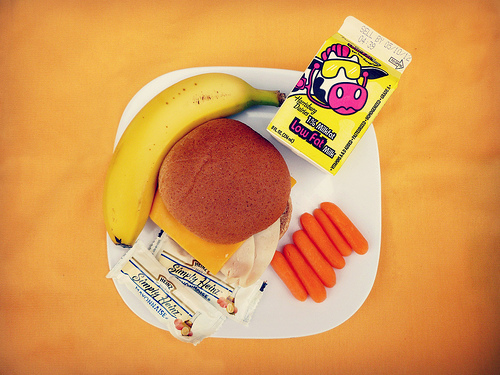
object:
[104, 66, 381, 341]
plate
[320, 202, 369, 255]
carrot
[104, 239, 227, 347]
packet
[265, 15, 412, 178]
box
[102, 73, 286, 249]
banana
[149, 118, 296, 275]
sandwich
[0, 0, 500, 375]
table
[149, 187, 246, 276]
cheese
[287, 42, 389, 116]
cow